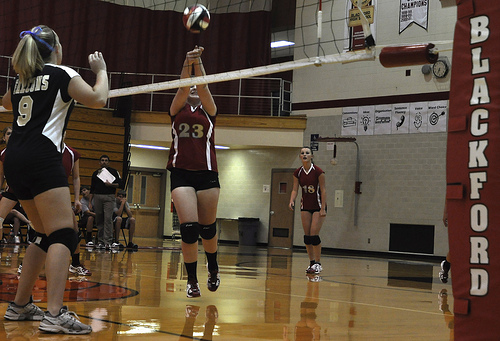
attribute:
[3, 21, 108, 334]
teen girl — white 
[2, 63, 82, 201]
uniform — black 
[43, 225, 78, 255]
pad — small, black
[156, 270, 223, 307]
sneakers — athletic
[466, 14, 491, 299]
letters — black, white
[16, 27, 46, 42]
ribbon — blue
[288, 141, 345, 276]
girl — teen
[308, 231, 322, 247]
knee pad — small, black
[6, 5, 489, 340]
volleyball — girls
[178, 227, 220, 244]
pad — black, small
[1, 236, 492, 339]
floor — polished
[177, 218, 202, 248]
knee pad — volleyball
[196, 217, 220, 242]
knee pad — volleyball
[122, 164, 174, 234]
doors — double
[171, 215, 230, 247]
knee pads — black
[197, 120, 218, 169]
stripe — white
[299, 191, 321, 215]
shorts — black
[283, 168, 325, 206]
top — red